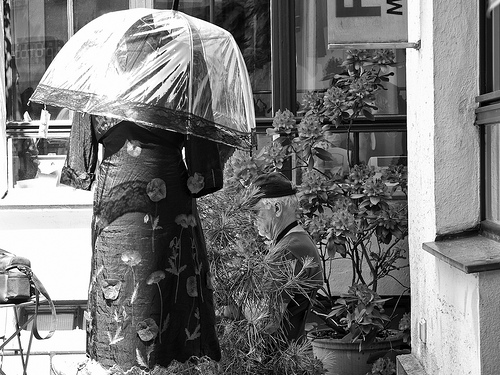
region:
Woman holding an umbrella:
[42, 26, 295, 365]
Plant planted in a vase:
[285, 72, 422, 341]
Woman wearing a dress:
[62, 80, 232, 371]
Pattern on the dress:
[122, 173, 214, 336]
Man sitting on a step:
[223, 170, 345, 369]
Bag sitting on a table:
[7, 247, 72, 369]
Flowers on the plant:
[283, 65, 408, 267]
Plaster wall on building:
[415, 49, 495, 226]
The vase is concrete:
[297, 327, 434, 365]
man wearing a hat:
[239, 162, 307, 246]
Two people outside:
[46, 2, 338, 373]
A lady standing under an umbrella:
[25, 0, 269, 371]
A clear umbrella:
[29, 0, 279, 161]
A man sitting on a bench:
[211, 172, 329, 354]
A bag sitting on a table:
[0, 234, 62, 353]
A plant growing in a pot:
[266, 38, 408, 364]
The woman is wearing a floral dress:
[56, 112, 239, 373]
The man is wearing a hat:
[235, 167, 296, 203]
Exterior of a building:
[401, 2, 499, 370]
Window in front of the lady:
[3, 0, 325, 148]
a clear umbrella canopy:
[30, 7, 258, 153]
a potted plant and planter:
[307, 163, 407, 373]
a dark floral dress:
[61, 113, 222, 365]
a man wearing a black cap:
[241, 173, 297, 207]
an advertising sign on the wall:
[325, 1, 416, 49]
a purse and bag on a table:
[1, 249, 58, 341]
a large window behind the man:
[241, 0, 299, 122]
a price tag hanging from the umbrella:
[38, 102, 51, 140]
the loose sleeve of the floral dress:
[58, 109, 95, 191]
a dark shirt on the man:
[268, 232, 323, 332]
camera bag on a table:
[1, 242, 65, 345]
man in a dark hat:
[234, 163, 322, 317]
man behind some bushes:
[228, 154, 330, 323]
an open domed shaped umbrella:
[33, 3, 295, 174]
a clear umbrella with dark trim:
[25, 0, 280, 177]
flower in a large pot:
[281, 47, 404, 370]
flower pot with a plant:
[280, 32, 408, 372]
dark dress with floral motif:
[58, 97, 228, 365]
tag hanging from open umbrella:
[20, 2, 77, 152]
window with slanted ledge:
[423, 1, 498, 282]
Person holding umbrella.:
[76, 28, 242, 138]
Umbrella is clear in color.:
[96, 33, 276, 130]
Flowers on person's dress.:
[86, 203, 206, 328]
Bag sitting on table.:
[3, 257, 73, 342]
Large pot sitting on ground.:
[305, 299, 372, 368]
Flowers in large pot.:
[286, 119, 368, 324]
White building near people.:
[421, 128, 450, 212]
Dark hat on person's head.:
[247, 180, 305, 210]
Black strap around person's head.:
[276, 212, 323, 244]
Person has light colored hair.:
[268, 192, 318, 202]